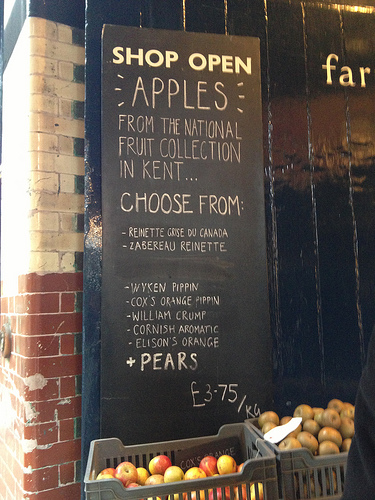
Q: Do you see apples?
A: Yes, there is an apple.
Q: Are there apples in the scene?
A: Yes, there is an apple.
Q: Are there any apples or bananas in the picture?
A: Yes, there is an apple.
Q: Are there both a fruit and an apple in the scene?
A: Yes, there are both an apple and a fruit.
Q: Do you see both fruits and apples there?
A: Yes, there are both an apple and a fruit.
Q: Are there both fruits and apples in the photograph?
A: Yes, there are both an apple and a fruit.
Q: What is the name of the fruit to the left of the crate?
A: The fruit is an apple.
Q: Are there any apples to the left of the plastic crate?
A: Yes, there is an apple to the left of the crate.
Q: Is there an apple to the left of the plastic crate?
A: Yes, there is an apple to the left of the crate.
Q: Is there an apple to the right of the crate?
A: No, the apple is to the left of the crate.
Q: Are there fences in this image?
A: No, there are no fences.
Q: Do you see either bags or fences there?
A: No, there are no fences or bags.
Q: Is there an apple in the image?
A: Yes, there is an apple.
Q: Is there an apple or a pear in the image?
A: Yes, there is an apple.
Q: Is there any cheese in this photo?
A: No, there is no cheese.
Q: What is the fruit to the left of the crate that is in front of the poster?
A: The fruit is an apple.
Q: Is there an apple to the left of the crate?
A: Yes, there is an apple to the left of the crate.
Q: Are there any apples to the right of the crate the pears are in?
A: No, the apple is to the left of the crate.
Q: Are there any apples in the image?
A: Yes, there is an apple.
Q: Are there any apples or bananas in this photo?
A: Yes, there is an apple.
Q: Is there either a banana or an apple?
A: Yes, there is an apple.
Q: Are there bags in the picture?
A: No, there are no bags.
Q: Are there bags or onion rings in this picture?
A: No, there are no bags or onion rings.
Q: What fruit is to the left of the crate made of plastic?
A: The fruit is an apple.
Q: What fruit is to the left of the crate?
A: The fruit is an apple.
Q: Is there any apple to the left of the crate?
A: Yes, there is an apple to the left of the crate.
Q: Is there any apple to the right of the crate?
A: No, the apple is to the left of the crate.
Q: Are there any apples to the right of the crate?
A: No, the apple is to the left of the crate.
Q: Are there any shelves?
A: No, there are no shelves.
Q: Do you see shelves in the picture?
A: No, there are no shelves.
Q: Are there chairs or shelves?
A: No, there are no shelves or chairs.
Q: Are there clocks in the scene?
A: No, there are no clocks.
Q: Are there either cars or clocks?
A: No, there are no clocks or cars.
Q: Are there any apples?
A: Yes, there is an apple.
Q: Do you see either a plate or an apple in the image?
A: Yes, there is an apple.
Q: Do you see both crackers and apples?
A: No, there is an apple but no crackers.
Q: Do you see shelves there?
A: No, there are no shelves.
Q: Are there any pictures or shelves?
A: No, there are no shelves or pictures.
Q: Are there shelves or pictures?
A: No, there are no shelves or pictures.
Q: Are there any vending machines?
A: No, there are no vending machines.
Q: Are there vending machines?
A: No, there are no vending machines.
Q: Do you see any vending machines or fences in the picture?
A: No, there are no vending machines or fences.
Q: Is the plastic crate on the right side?
A: Yes, the crate is on the right of the image.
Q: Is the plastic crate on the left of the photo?
A: No, the crate is on the right of the image.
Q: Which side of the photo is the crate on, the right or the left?
A: The crate is on the right of the image.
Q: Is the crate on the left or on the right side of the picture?
A: The crate is on the right of the image.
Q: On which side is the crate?
A: The crate is on the right of the image.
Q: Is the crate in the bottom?
A: Yes, the crate is in the bottom of the image.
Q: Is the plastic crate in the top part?
A: No, the crate is in the bottom of the image.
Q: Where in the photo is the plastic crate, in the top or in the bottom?
A: The crate is in the bottom of the image.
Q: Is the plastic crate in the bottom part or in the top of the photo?
A: The crate is in the bottom of the image.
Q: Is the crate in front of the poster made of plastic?
A: Yes, the crate is made of plastic.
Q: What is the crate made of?
A: The crate is made of plastic.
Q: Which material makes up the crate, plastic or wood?
A: The crate is made of plastic.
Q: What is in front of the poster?
A: The crate is in front of the poster.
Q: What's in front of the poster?
A: The crate is in front of the poster.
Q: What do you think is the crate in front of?
A: The crate is in front of the poster.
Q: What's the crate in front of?
A: The crate is in front of the poster.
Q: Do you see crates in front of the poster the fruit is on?
A: Yes, there is a crate in front of the poster.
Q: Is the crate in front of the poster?
A: Yes, the crate is in front of the poster.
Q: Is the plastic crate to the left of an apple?
A: No, the crate is to the right of an apple.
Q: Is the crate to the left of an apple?
A: No, the crate is to the right of an apple.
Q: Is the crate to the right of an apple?
A: Yes, the crate is to the right of an apple.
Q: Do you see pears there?
A: Yes, there are pears.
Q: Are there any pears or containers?
A: Yes, there are pears.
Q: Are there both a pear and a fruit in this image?
A: Yes, there are both a pear and a fruit.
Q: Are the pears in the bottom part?
A: Yes, the pears are in the bottom of the image.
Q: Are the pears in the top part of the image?
A: No, the pears are in the bottom of the image.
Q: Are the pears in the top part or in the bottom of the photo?
A: The pears are in the bottom of the image.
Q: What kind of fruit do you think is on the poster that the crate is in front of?
A: The fruits are pears.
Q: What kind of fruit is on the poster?
A: The fruits are pears.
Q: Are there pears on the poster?
A: Yes, there are pears on the poster.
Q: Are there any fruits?
A: Yes, there is a fruit.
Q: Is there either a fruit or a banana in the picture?
A: Yes, there is a fruit.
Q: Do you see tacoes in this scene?
A: No, there are no tacoes.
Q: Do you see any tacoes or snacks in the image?
A: No, there are no tacoes or snacks.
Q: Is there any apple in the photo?
A: Yes, there is an apple.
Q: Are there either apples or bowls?
A: Yes, there is an apple.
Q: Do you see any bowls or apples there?
A: Yes, there is an apple.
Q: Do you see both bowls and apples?
A: No, there is an apple but no bowls.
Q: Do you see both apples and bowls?
A: No, there is an apple but no bowls.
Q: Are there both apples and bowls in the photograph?
A: No, there is an apple but no bowls.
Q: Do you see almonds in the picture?
A: No, there are no almonds.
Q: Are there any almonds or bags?
A: No, there are no almonds or bags.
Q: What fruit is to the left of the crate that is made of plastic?
A: The fruit is an apple.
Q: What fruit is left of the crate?
A: The fruit is an apple.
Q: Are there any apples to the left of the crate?
A: Yes, there is an apple to the left of the crate.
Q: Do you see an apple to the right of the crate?
A: No, the apple is to the left of the crate.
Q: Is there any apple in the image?
A: Yes, there is an apple.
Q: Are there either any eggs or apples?
A: Yes, there is an apple.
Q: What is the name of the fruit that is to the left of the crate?
A: The fruit is an apple.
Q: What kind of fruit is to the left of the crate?
A: The fruit is an apple.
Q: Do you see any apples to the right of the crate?
A: No, the apple is to the left of the crate.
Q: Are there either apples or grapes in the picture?
A: Yes, there are apples.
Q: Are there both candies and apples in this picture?
A: No, there are apples but no candies.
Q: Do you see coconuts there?
A: No, there are no coconuts.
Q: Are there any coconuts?
A: No, there are no coconuts.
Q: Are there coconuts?
A: No, there are no coconuts.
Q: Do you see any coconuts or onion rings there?
A: No, there are no coconuts or onion rings.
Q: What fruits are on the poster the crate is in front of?
A: The fruits are apples.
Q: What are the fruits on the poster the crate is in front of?
A: The fruits are apples.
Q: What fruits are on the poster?
A: The fruits are apples.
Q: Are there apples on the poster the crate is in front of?
A: Yes, there are apples on the poster.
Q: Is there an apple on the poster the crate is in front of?
A: Yes, there are apples on the poster.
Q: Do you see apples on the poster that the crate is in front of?
A: Yes, there are apples on the poster.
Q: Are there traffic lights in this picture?
A: No, there are no traffic lights.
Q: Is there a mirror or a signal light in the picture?
A: No, there are no traffic lights or mirrors.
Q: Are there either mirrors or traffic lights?
A: No, there are no traffic lights or mirrors.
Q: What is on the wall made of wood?
A: The poster is on the wall.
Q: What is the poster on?
A: The poster is on the wall.